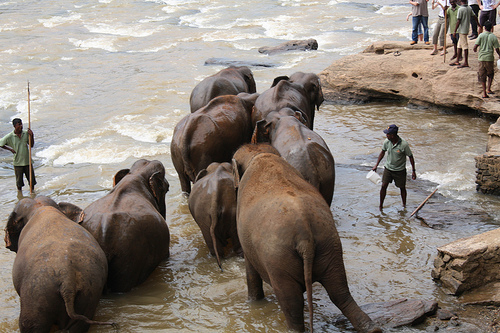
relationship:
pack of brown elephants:
[174, 65, 345, 332] [5, 160, 171, 331]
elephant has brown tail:
[1, 192, 107, 332] [63, 290, 78, 320]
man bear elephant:
[372, 126, 416, 213] [1, 192, 107, 332]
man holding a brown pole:
[372, 126, 416, 213] [27, 84, 32, 182]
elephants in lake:
[5, 160, 171, 331] [0, 0, 500, 223]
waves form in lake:
[197, 20, 250, 45] [0, 0, 500, 223]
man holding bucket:
[372, 126, 416, 213] [368, 170, 383, 184]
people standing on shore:
[407, 2, 498, 84] [335, 57, 441, 99]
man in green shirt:
[372, 126, 416, 213] [385, 142, 406, 169]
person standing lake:
[1, 118, 35, 189] [0, 0, 500, 223]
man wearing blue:
[372, 126, 416, 213] [383, 124, 398, 134]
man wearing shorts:
[372, 126, 416, 213] [382, 169, 408, 190]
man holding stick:
[372, 126, 416, 213] [27, 84, 32, 182]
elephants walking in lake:
[5, 160, 171, 331] [0, 0, 500, 223]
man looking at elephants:
[372, 126, 416, 213] [5, 160, 171, 331]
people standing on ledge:
[407, 2, 498, 84] [434, 96, 483, 114]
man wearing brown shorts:
[372, 126, 416, 213] [382, 169, 408, 190]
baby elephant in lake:
[190, 161, 235, 256] [0, 0, 500, 223]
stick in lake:
[409, 187, 436, 219] [0, 0, 500, 223]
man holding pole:
[372, 126, 416, 213] [27, 84, 32, 182]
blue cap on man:
[390, 127, 396, 131] [372, 126, 416, 213]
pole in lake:
[27, 84, 32, 182] [0, 0, 500, 223]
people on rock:
[407, 2, 498, 84] [375, 39, 409, 61]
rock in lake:
[253, 37, 320, 56] [0, 0, 500, 223]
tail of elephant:
[63, 290, 78, 320] [1, 192, 107, 332]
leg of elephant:
[334, 303, 381, 330] [1, 192, 107, 332]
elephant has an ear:
[1, 192, 107, 332] [313, 84, 323, 111]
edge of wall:
[471, 155, 487, 192] [471, 254, 498, 283]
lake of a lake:
[0, 0, 500, 223] [0, 0, 500, 223]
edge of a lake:
[471, 155, 487, 192] [330, 116, 372, 149]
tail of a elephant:
[63, 290, 78, 320] [1, 192, 107, 332]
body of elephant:
[185, 113, 243, 144] [1, 192, 107, 332]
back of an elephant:
[260, 161, 288, 215] [1, 192, 107, 332]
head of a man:
[12, 117, 24, 132] [372, 126, 416, 213]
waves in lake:
[197, 20, 250, 45] [0, 0, 500, 223]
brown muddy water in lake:
[23, 40, 55, 65] [0, 0, 500, 223]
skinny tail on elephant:
[212, 240, 221, 270] [1, 192, 107, 332]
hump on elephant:
[273, 79, 285, 105] [1, 192, 107, 332]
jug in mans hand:
[368, 170, 383, 184] [411, 171, 418, 181]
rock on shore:
[253, 37, 320, 56] [335, 57, 441, 99]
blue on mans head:
[383, 124, 398, 134] [12, 117, 24, 132]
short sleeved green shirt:
[405, 145, 413, 157] [385, 142, 406, 169]